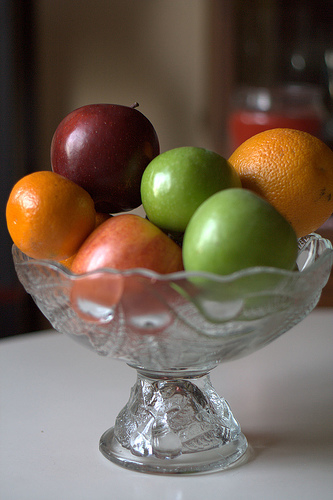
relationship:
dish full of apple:
[12, 207, 331, 476] [50, 102, 159, 214]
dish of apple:
[12, 207, 331, 476] [50, 102, 159, 214]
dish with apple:
[12, 207, 331, 476] [50, 102, 159, 214]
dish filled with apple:
[12, 207, 331, 476] [50, 102, 159, 214]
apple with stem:
[50, 102, 159, 214] [128, 99, 141, 110]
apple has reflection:
[50, 102, 159, 214] [10, 185, 44, 226]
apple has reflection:
[50, 102, 159, 214] [62, 121, 92, 170]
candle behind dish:
[225, 82, 321, 157] [12, 207, 331, 476]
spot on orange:
[312, 183, 332, 206] [228, 127, 331, 238]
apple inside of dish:
[68, 211, 198, 335] [12, 207, 331, 476]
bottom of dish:
[97, 371, 247, 475] [12, 207, 331, 476]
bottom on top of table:
[97, 371, 247, 475] [0, 309, 332, 498]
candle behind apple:
[225, 82, 321, 157] [50, 102, 159, 214]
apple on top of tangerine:
[50, 102, 159, 214] [5, 170, 95, 262]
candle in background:
[225, 82, 321, 157] [1, 0, 332, 298]